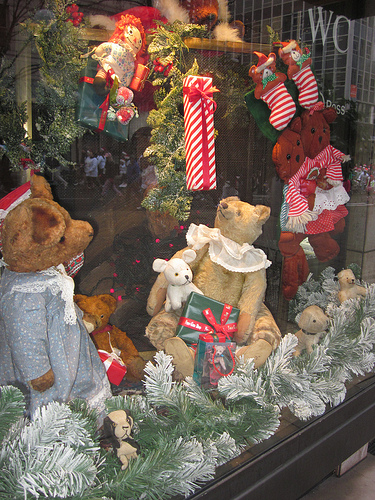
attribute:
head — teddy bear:
[272, 35, 304, 63]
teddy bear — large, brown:
[6, 174, 130, 435]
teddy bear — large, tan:
[143, 195, 283, 383]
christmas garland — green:
[142, 26, 251, 229]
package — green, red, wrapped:
[174, 290, 240, 343]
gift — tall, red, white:
[167, 66, 230, 203]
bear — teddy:
[243, 52, 298, 101]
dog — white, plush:
[152, 249, 205, 311]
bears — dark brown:
[262, 116, 367, 295]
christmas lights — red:
[106, 223, 186, 302]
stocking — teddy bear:
[246, 50, 296, 132]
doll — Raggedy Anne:
[95, 16, 154, 91]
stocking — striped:
[261, 83, 295, 129]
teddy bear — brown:
[78, 295, 154, 383]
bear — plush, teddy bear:
[78, 290, 140, 374]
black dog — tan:
[105, 408, 141, 470]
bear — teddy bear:
[2, 166, 140, 365]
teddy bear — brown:
[74, 294, 156, 386]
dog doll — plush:
[102, 409, 145, 469]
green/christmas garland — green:
[2, 279, 373, 498]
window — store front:
[1, 2, 363, 498]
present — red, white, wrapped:
[181, 74, 219, 191]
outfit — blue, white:
[0, 260, 117, 439]